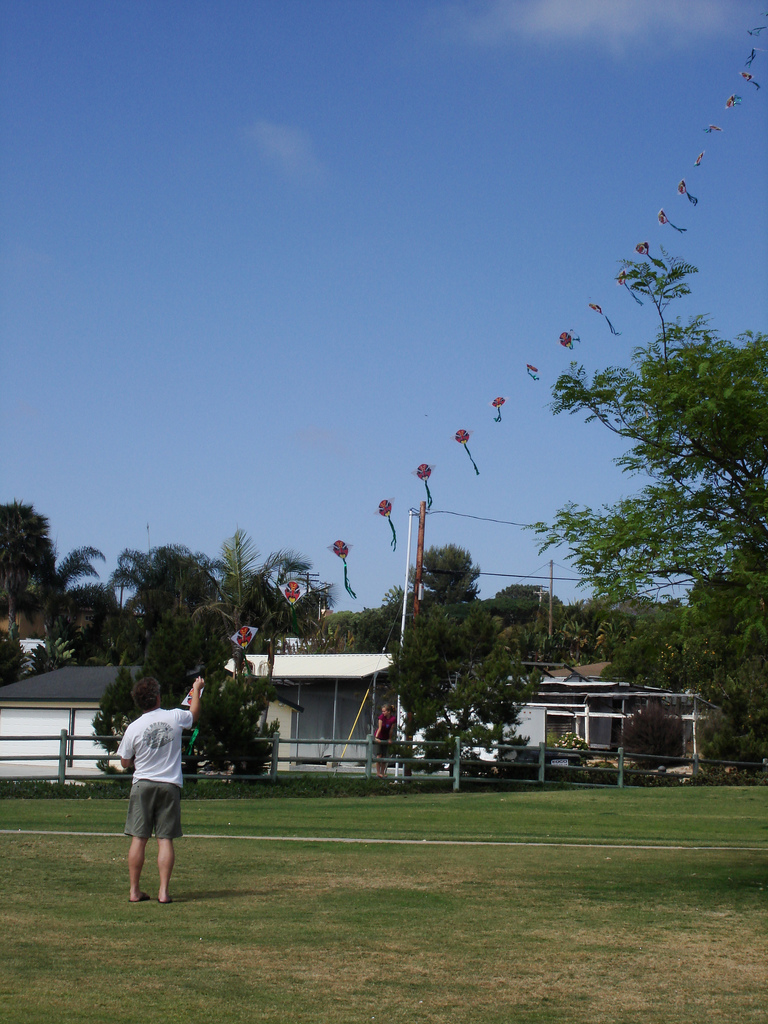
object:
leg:
[151, 824, 183, 911]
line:
[0, 822, 767, 855]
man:
[113, 674, 213, 907]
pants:
[123, 772, 189, 848]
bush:
[617, 688, 690, 775]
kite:
[277, 570, 320, 642]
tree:
[202, 652, 279, 783]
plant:
[549, 718, 584, 754]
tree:
[88, 660, 168, 778]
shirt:
[373, 714, 398, 746]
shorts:
[373, 729, 394, 758]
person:
[110, 662, 224, 908]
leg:
[119, 802, 153, 911]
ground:
[1, 799, 765, 1021]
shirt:
[116, 701, 199, 788]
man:
[114, 663, 213, 907]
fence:
[7, 733, 765, 807]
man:
[114, 673, 217, 908]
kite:
[585, 293, 628, 343]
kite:
[669, 175, 704, 210]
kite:
[321, 529, 365, 603]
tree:
[531, 228, 725, 792]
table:
[532, 744, 583, 777]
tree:
[464, 614, 541, 781]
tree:
[538, 239, 767, 754]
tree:
[1, 493, 68, 687]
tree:
[405, 536, 484, 668]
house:
[0, 655, 308, 784]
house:
[440, 640, 737, 771]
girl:
[366, 698, 405, 774]